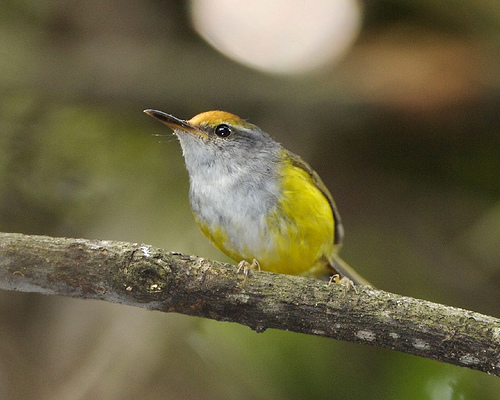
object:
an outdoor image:
[1, 1, 499, 400]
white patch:
[175, 130, 286, 258]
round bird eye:
[213, 123, 234, 140]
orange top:
[185, 109, 250, 126]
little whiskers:
[151, 131, 180, 144]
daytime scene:
[1, 1, 499, 399]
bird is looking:
[141, 103, 286, 166]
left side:
[0, 0, 240, 337]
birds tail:
[326, 253, 376, 288]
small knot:
[123, 260, 175, 302]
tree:
[6, 224, 500, 372]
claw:
[235, 258, 261, 282]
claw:
[327, 273, 362, 298]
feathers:
[319, 249, 373, 290]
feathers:
[214, 150, 247, 215]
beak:
[142, 107, 208, 139]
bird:
[141, 107, 376, 297]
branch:
[0, 230, 500, 378]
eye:
[213, 124, 232, 138]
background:
[1, 0, 498, 398]